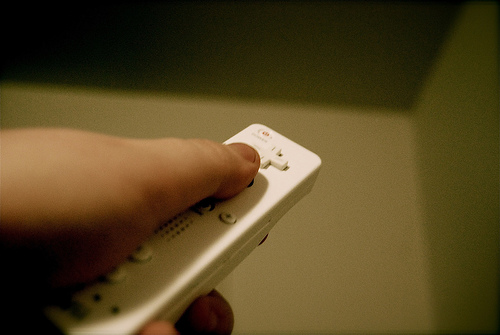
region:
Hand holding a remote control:
[170, 241, 197, 266]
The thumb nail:
[237, 146, 247, 151]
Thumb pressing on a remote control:
[228, 146, 250, 167]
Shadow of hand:
[165, 247, 177, 269]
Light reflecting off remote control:
[278, 176, 290, 188]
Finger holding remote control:
[195, 302, 210, 317]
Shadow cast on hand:
[16, 248, 47, 268]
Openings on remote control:
[172, 223, 183, 231]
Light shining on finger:
[149, 327, 163, 332]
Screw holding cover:
[224, 213, 231, 220]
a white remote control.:
[46, 122, 342, 333]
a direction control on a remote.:
[252, 140, 295, 176]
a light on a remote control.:
[255, 118, 275, 146]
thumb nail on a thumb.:
[210, 131, 272, 187]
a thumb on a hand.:
[0, 70, 301, 299]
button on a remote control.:
[206, 209, 253, 234]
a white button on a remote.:
[120, 229, 165, 270]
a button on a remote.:
[97, 253, 137, 287]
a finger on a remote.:
[169, 280, 261, 333]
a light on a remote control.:
[77, 270, 117, 311]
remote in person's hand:
[58, 113, 375, 311]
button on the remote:
[218, 209, 250, 229]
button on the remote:
[258, 142, 290, 174]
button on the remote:
[135, 248, 155, 267]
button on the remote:
[114, 265, 136, 285]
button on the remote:
[100, 255, 124, 282]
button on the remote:
[268, 155, 289, 180]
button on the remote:
[137, 245, 152, 261]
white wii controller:
[41, 120, 322, 332]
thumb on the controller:
[210, 131, 261, 186]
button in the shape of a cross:
[251, 141, 292, 173]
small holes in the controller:
[146, 210, 195, 246]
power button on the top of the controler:
[252, 125, 273, 141]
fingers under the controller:
[137, 293, 231, 333]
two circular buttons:
[100, 243, 155, 285]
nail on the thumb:
[223, 133, 263, 172]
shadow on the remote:
[68, 154, 283, 320]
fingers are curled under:
[136, 291, 233, 333]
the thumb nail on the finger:
[217, 138, 258, 188]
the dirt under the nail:
[243, 143, 260, 162]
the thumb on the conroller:
[120, 126, 260, 207]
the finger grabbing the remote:
[146, 281, 233, 334]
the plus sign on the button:
[218, 204, 238, 230]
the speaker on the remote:
[155, 207, 194, 242]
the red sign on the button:
[258, 125, 273, 140]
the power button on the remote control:
[256, 125, 271, 143]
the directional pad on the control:
[255, 138, 290, 173]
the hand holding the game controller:
[5, 55, 327, 333]